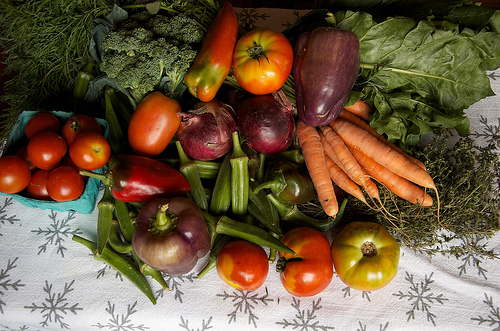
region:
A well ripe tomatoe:
[18, 115, 63, 164]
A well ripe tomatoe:
[47, 169, 77, 194]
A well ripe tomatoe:
[73, 143, 109, 168]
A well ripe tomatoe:
[6, 155, 30, 195]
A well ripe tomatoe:
[220, 251, 264, 287]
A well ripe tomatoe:
[278, 239, 317, 290]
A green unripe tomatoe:
[324, 225, 403, 282]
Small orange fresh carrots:
[298, 124, 448, 209]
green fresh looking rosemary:
[15, 62, 72, 102]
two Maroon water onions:
[186, 103, 296, 151]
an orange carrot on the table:
[291, 111, 341, 220]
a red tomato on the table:
[22, 121, 69, 171]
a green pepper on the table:
[91, 185, 118, 259]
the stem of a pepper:
[76, 163, 113, 190]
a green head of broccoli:
[89, 18, 195, 105]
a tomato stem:
[272, 252, 288, 275]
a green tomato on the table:
[328, 218, 401, 293]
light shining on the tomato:
[40, 146, 56, 167]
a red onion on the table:
[172, 98, 237, 162]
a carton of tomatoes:
[0, 105, 115, 217]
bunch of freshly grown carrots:
[293, 99, 443, 226]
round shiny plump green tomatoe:
[331, 215, 399, 291]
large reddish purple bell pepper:
[132, 192, 217, 284]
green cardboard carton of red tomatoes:
[5, 105, 116, 216]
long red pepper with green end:
[190, 4, 238, 109]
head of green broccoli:
[103, 7, 213, 104]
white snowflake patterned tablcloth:
[6, 70, 499, 327]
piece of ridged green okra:
[225, 127, 250, 211]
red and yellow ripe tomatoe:
[230, 24, 297, 94]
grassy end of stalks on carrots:
[373, 125, 499, 241]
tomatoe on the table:
[242, 31, 292, 96]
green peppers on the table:
[90, 206, 145, 281]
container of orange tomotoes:
[8, 105, 105, 205]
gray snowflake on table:
[407, 264, 449, 327]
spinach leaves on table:
[370, 23, 493, 127]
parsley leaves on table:
[456, 179, 492, 255]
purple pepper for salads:
[130, 199, 232, 283]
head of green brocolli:
[105, 25, 226, 94]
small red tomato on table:
[222, 241, 263, 289]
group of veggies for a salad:
[24, 11, 440, 266]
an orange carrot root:
[293, 117, 340, 215]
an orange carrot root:
[323, 155, 368, 206]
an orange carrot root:
[321, 124, 370, 189]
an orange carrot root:
[340, 140, 434, 206]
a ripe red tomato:
[274, 223, 334, 299]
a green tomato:
[334, 220, 399, 290]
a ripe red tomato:
[216, 237, 268, 288]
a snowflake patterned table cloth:
[0, 67, 495, 327]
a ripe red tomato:
[69, 131, 111, 167]